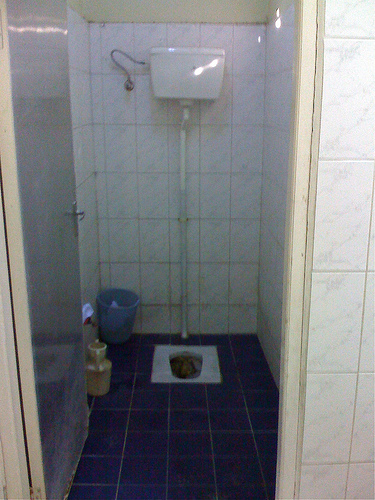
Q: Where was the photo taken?
A: It was taken at the bathroom.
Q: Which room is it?
A: It is a bathroom.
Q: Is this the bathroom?
A: Yes, it is the bathroom.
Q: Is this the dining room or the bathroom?
A: It is the bathroom.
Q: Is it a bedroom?
A: No, it is a bathroom.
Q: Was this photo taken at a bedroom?
A: No, the picture was taken in a bathroom.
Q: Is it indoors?
A: Yes, it is indoors.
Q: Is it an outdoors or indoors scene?
A: It is indoors.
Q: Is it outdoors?
A: No, it is indoors.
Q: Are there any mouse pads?
A: No, there are no mouse pads.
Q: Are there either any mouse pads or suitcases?
A: No, there are no mouse pads or suitcases.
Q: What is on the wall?
A: The pipe is on the wall.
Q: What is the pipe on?
A: The pipe is on the wall.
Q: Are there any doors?
A: Yes, there is a door.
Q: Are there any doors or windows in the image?
A: Yes, there is a door.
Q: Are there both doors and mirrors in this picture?
A: No, there is a door but no mirrors.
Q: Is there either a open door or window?
A: Yes, there is an open door.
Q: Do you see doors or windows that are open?
A: Yes, the door is open.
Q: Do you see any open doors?
A: Yes, there is an open door.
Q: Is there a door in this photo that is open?
A: Yes, there is a door that is open.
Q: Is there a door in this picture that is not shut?
A: Yes, there is a open door.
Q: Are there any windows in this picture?
A: No, there are no windows.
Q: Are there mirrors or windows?
A: No, there are no windows or mirrors.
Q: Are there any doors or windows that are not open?
A: No, there is a door but it is open.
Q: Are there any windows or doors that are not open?
A: No, there is a door but it is open.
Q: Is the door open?
A: Yes, the door is open.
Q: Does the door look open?
A: Yes, the door is open.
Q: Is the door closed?
A: No, the door is open.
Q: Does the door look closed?
A: No, the door is open.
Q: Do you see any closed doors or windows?
A: No, there is a door but it is open.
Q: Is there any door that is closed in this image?
A: No, there is a door but it is open.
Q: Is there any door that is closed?
A: No, there is a door but it is open.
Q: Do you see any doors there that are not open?
A: No, there is a door but it is open.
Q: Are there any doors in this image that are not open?
A: No, there is a door but it is open.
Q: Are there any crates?
A: No, there are no crates.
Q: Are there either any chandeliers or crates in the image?
A: No, there are no crates or chandeliers.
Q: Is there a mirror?
A: No, there are no mirrors.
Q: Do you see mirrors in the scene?
A: No, there are no mirrors.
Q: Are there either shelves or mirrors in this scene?
A: No, there are no mirrors or shelves.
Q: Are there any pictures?
A: No, there are no pictures.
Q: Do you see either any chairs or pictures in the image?
A: No, there are no pictures or chairs.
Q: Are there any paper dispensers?
A: No, there are no paper dispensers.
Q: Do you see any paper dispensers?
A: No, there are no paper dispensers.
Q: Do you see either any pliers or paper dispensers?
A: No, there are no paper dispensers or pliers.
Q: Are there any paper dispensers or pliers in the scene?
A: No, there are no paper dispensers or pliers.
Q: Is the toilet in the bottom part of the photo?
A: Yes, the toilet is in the bottom of the image.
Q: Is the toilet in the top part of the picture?
A: No, the toilet is in the bottom of the image.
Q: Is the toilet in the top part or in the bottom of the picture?
A: The toilet is in the bottom of the image.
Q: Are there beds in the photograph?
A: No, there are no beds.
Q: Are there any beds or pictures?
A: No, there are no beds or pictures.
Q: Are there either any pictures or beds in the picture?
A: No, there are no beds or pictures.